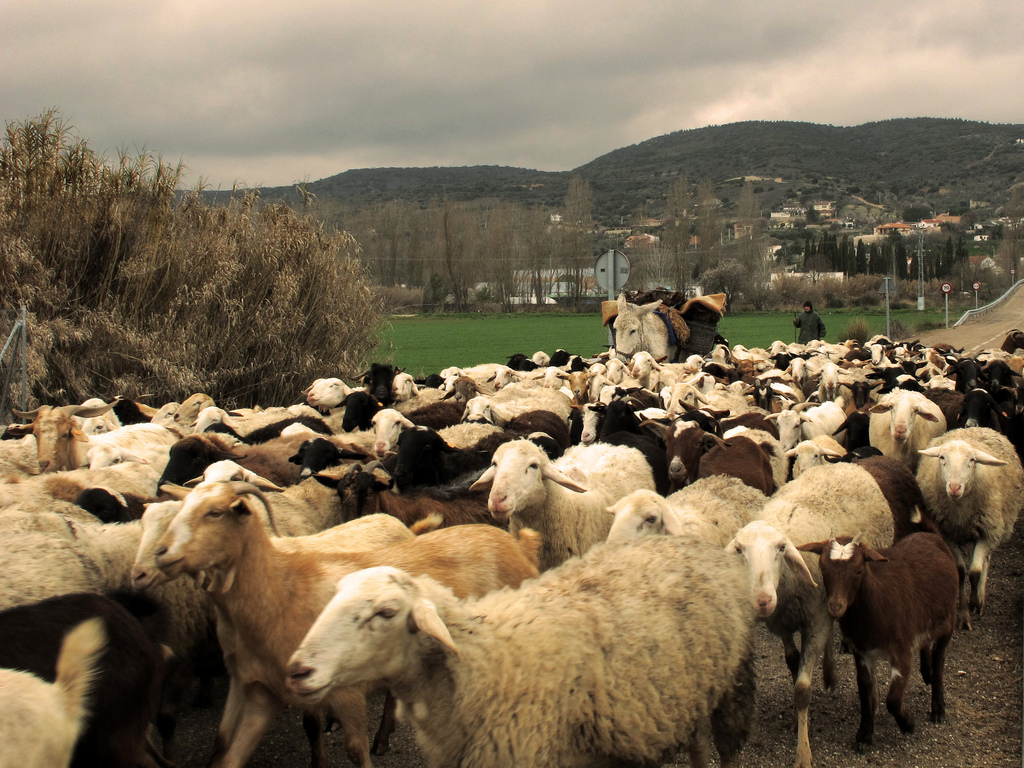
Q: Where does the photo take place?
A: In the countryside.